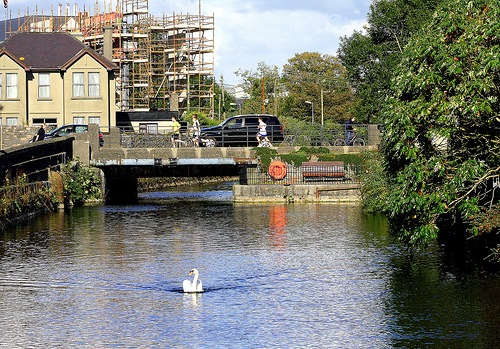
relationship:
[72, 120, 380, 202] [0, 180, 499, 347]
bridge over water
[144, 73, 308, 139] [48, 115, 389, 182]
people on bridge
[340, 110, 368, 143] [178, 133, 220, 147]
person riding bicycle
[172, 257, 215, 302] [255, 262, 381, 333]
swan on water